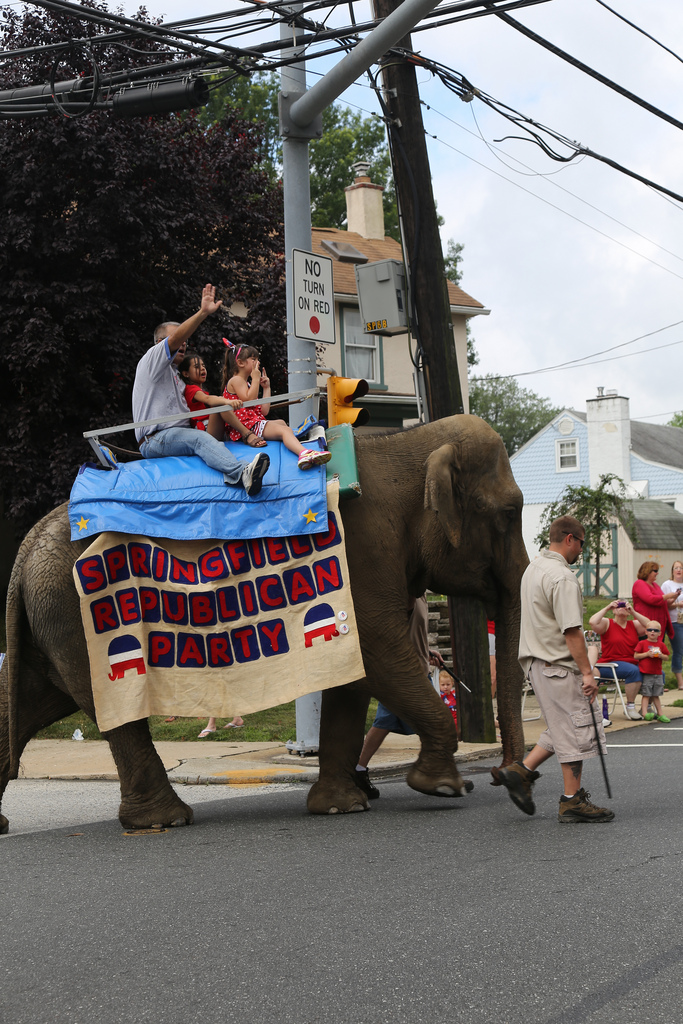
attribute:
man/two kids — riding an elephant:
[131, 278, 334, 506]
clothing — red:
[599, 581, 669, 675]